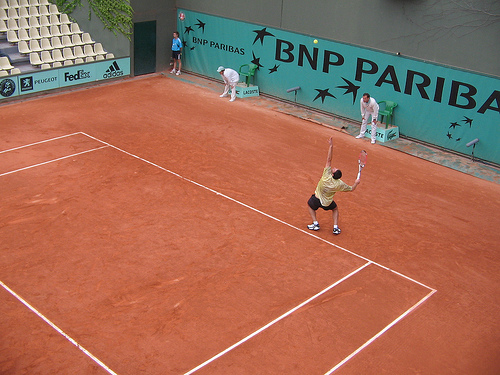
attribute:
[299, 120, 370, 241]
man — playing, swinging, serving, male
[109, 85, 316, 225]
court — dirt, clay, red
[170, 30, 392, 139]
people — standing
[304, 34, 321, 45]
ball — yellow, small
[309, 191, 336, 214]
shorts — black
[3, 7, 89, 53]
seats — empty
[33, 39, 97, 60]
chairs — cream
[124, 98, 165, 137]
ground — reddish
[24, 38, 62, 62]
rows — empty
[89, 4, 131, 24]
ivy — green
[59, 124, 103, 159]
lines — white, chalked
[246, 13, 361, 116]
wall — green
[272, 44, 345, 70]
letters — black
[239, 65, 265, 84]
chair — green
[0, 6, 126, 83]
stands — empty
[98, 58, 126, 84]
addidas — black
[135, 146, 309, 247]
line — long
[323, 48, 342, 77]
letter — black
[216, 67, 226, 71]
cap — blue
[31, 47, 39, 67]
seat — white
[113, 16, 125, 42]
leaves — green